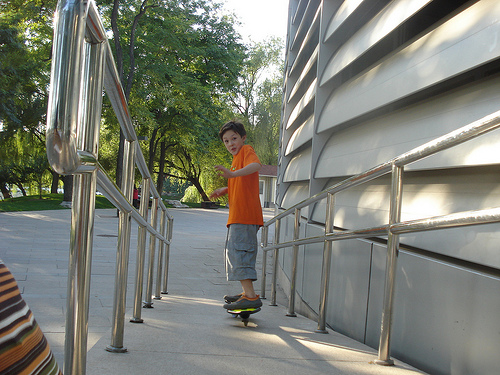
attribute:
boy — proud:
[205, 103, 265, 328]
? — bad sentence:
[346, 243, 494, 278]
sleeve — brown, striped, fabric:
[0, 258, 65, 373]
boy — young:
[208, 114, 286, 314]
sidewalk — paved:
[80, 288, 431, 373]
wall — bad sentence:
[272, 210, 489, 364]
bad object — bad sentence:
[81, 123, 243, 195]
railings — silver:
[38, 15, 175, 372]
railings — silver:
[261, 109, 498, 364]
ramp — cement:
[91, 294, 426, 374]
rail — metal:
[254, 107, 497, 374]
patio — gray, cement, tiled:
[66, 279, 465, 373]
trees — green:
[5, 0, 232, 187]